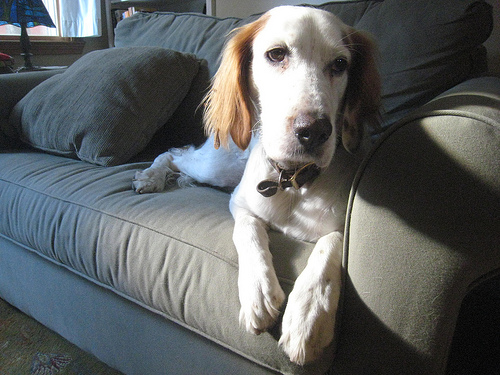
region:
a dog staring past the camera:
[147, 9, 416, 347]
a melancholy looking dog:
[156, 0, 461, 321]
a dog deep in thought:
[107, 25, 413, 348]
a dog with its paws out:
[120, 12, 480, 373]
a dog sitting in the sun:
[104, 19, 463, 354]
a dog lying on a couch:
[151, 2, 432, 327]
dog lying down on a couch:
[113, 27, 493, 365]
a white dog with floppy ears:
[142, 18, 439, 304]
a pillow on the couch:
[35, 32, 312, 348]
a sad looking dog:
[180, 0, 414, 342]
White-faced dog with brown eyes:
[248, 22, 347, 141]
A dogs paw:
[289, 275, 340, 369]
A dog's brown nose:
[296, 112, 333, 148]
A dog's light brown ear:
[214, 26, 258, 132]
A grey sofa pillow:
[56, 55, 144, 150]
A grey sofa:
[52, 52, 404, 315]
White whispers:
[341, 35, 357, 47]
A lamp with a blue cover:
[12, 6, 62, 69]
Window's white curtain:
[64, 12, 119, 42]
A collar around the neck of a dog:
[262, 161, 314, 195]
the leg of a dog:
[235, 212, 285, 339]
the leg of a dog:
[279, 226, 343, 353]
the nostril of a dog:
[296, 125, 309, 141]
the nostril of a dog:
[314, 125, 324, 142]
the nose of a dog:
[293, 114, 331, 149]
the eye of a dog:
[261, 46, 288, 69]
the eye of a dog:
[325, 49, 350, 74]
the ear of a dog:
[209, 25, 255, 149]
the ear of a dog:
[341, 15, 381, 141]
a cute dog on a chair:
[124, 0, 399, 353]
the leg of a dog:
[132, 140, 173, 192]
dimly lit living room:
[0, 0, 497, 374]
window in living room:
[1, 0, 105, 40]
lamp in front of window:
[0, 2, 57, 72]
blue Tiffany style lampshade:
[0, 1, 57, 28]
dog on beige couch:
[133, 3, 375, 368]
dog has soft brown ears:
[195, 16, 382, 153]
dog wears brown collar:
[256, 158, 321, 195]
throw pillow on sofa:
[12, 45, 207, 167]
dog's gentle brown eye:
[264, 45, 290, 62]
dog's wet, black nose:
[296, 111, 335, 146]